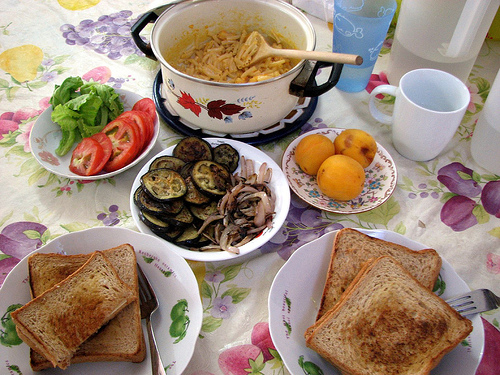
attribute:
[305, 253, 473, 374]
toast — square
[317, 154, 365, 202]
fruit — orange, brown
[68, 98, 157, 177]
tomato — sliced, red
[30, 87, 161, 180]
bowl — white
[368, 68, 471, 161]
cup — white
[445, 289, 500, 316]
fork — silver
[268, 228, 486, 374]
bowl — white, green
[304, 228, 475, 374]
bread — toasted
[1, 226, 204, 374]
bowl — white, green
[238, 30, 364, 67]
spoon — wooden